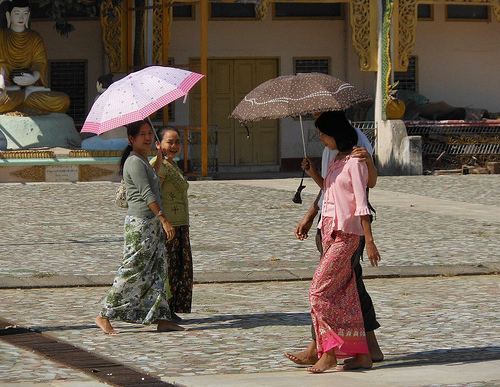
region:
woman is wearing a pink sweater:
[315, 150, 370, 240]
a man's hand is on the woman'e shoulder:
[348, 144, 372, 164]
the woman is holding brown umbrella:
[232, 69, 372, 122]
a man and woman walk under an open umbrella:
[228, 70, 400, 370]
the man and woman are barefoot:
[284, 110, 392, 370]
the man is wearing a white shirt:
[319, 129, 375, 206]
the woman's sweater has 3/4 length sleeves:
[354, 206, 385, 246]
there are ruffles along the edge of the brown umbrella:
[223, 95, 374, 122]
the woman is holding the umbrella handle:
[295, 110, 310, 172]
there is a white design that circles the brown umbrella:
[235, 82, 360, 106]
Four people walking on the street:
[62, 45, 414, 377]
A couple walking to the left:
[228, 54, 417, 376]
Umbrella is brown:
[226, 59, 367, 180]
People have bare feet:
[60, 51, 402, 383]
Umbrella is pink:
[71, 56, 205, 171]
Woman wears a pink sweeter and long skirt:
[293, 104, 391, 379]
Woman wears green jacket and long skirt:
[82, 107, 187, 349]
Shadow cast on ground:
[388, 316, 497, 383]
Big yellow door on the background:
[176, 51, 287, 176]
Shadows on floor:
[180, 293, 314, 340]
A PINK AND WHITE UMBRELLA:
[71, 60, 218, 142]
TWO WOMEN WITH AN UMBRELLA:
[72, 57, 236, 342]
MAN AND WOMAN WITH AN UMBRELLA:
[221, 61, 412, 376]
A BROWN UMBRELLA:
[226, 65, 377, 141]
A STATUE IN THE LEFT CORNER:
[0, 4, 81, 124]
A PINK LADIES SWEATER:
[314, 151, 406, 247]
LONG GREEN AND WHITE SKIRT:
[91, 208, 177, 332]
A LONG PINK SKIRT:
[306, 216, 396, 370]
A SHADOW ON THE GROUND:
[161, 303, 396, 335]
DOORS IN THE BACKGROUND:
[175, 53, 315, 183]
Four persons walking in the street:
[68, 50, 413, 371]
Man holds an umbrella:
[234, 66, 402, 370]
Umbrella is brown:
[231, 61, 373, 178]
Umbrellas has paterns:
[221, 57, 372, 207]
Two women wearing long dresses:
[69, 54, 213, 348]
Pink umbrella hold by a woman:
[68, 51, 213, 145]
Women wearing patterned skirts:
[94, 111, 206, 342]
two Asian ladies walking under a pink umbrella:
[74, 51, 212, 343]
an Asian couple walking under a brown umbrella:
[227, 61, 409, 377]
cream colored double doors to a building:
[188, 61, 280, 171]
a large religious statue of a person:
[4, 3, 73, 118]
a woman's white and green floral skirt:
[100, 215, 172, 325]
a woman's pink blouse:
[315, 151, 380, 238]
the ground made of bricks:
[5, 190, 101, 284]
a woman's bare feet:
[87, 310, 199, 337]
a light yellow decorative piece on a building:
[345, 3, 380, 74]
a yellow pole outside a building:
[195, 6, 217, 178]